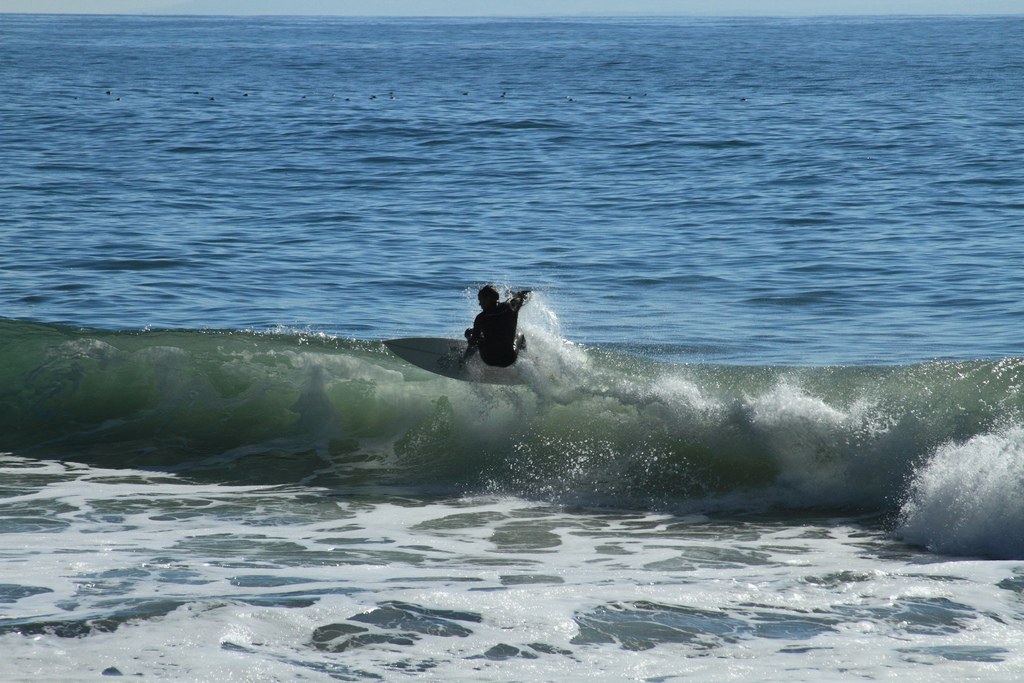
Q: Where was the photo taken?
A: It was taken at the ocean.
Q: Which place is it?
A: It is an ocean.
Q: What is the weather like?
A: It is clear.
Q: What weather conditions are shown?
A: It is clear.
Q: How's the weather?
A: It is clear.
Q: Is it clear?
A: Yes, it is clear.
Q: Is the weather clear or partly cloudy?
A: It is clear.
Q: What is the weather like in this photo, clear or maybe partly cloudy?
A: It is clear.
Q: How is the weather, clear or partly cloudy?
A: It is clear.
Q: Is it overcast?
A: No, it is clear.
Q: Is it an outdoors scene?
A: Yes, it is outdoors.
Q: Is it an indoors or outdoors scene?
A: It is outdoors.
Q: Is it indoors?
A: No, it is outdoors.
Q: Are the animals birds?
A: Yes, all the animals are birds.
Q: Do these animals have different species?
A: No, all the animals are birds.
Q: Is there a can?
A: No, there are no cans.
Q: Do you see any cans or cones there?
A: No, there are no cans or cones.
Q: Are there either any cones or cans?
A: No, there are no cans or cones.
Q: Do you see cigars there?
A: No, there are no cigars.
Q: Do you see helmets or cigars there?
A: No, there are no cigars or helmets.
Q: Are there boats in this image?
A: No, there are no boats.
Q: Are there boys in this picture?
A: No, there are no boys.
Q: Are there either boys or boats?
A: No, there are no boys or boats.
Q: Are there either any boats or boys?
A: No, there are no boys or boats.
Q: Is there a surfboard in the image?
A: Yes, there is a surfboard.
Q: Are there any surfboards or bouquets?
A: Yes, there is a surfboard.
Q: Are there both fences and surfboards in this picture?
A: No, there is a surfboard but no fences.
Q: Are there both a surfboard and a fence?
A: No, there is a surfboard but no fences.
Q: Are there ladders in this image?
A: No, there are no ladders.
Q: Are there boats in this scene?
A: No, there are no boats.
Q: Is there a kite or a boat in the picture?
A: No, there are no boats or kites.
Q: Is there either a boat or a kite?
A: No, there are no boats or kites.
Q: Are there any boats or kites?
A: No, there are no boats or kites.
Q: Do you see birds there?
A: Yes, there are birds.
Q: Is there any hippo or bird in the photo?
A: Yes, there are birds.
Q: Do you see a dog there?
A: No, there are no dogs.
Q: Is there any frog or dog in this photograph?
A: No, there are no dogs or frogs.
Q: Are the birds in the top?
A: Yes, the birds are in the top of the image.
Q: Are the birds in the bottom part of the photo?
A: No, the birds are in the top of the image.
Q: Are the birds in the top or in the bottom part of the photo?
A: The birds are in the top of the image.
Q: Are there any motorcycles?
A: No, there are no motorcycles.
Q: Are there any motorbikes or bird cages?
A: No, there are no motorbikes or bird cages.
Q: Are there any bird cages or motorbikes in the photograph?
A: No, there are no motorbikes or bird cages.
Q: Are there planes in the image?
A: No, there are no planes.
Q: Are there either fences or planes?
A: No, there are no planes or fences.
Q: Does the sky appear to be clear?
A: Yes, the sky is clear.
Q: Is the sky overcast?
A: No, the sky is clear.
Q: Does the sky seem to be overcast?
A: No, the sky is clear.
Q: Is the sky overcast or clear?
A: The sky is clear.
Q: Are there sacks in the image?
A: No, there are no sacks.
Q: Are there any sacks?
A: No, there are no sacks.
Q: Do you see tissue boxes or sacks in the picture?
A: No, there are no sacks or tissue boxes.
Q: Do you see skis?
A: No, there are no skis.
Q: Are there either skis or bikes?
A: No, there are no skis or bikes.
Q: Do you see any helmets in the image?
A: No, there are no helmets.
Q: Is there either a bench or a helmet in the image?
A: No, there are no helmets or benches.